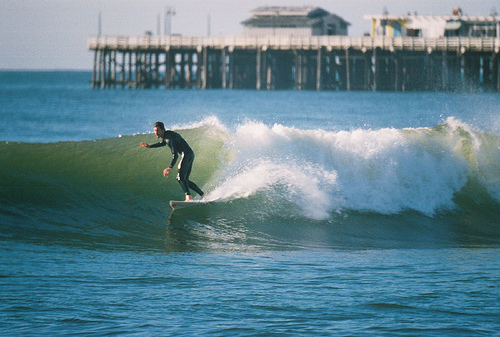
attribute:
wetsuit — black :
[143, 119, 213, 213]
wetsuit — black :
[145, 135, 208, 191]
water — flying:
[209, 163, 339, 226]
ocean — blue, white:
[0, 95, 499, 336]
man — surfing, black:
[140, 120, 208, 200]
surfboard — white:
[170, 199, 199, 210]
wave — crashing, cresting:
[3, 118, 499, 218]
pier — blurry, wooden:
[91, 34, 499, 95]